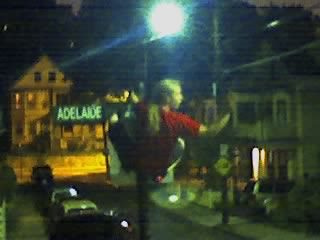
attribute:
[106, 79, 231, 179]
man — here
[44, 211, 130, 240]
car — parked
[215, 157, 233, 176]
sign — yellow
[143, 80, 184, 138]
hair — blond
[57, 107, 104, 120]
sign — adelaida, black, white, here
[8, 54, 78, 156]
building — white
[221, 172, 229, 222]
signpost — street signpost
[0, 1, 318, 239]
scene — night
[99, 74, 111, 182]
pole — utility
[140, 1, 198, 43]
light — bright, here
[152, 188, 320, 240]
sidewalk — gray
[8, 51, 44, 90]
roof — steep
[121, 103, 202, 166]
shirt — red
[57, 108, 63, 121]
letter — here